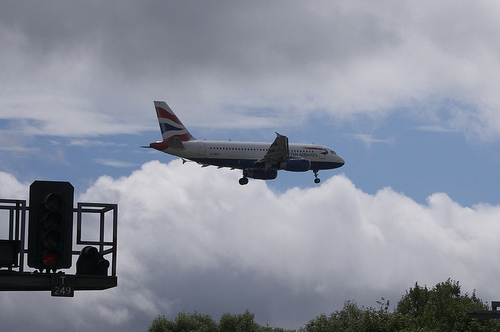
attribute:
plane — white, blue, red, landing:
[150, 100, 345, 186]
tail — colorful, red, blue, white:
[153, 100, 190, 140]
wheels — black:
[313, 173, 322, 184]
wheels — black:
[239, 169, 248, 186]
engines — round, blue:
[242, 156, 311, 179]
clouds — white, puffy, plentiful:
[3, 2, 499, 328]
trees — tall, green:
[144, 278, 499, 331]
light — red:
[30, 179, 75, 272]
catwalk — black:
[2, 199, 117, 291]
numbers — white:
[53, 273, 72, 296]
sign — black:
[52, 273, 74, 297]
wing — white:
[258, 133, 289, 169]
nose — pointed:
[337, 156, 345, 168]